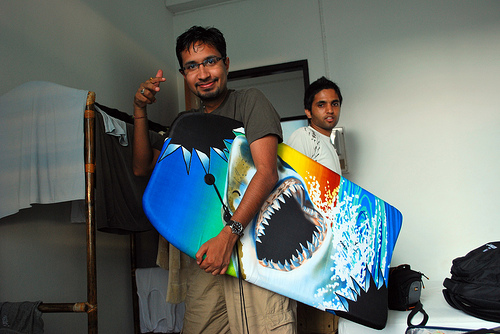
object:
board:
[136, 109, 404, 330]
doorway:
[226, 57, 308, 114]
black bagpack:
[441, 237, 498, 325]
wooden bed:
[0, 79, 167, 334]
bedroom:
[0, 0, 497, 334]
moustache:
[195, 77, 220, 90]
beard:
[197, 85, 220, 99]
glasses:
[179, 57, 226, 73]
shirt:
[285, 125, 348, 176]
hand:
[133, 68, 166, 107]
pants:
[182, 243, 299, 334]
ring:
[140, 88, 144, 93]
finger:
[149, 78, 166, 84]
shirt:
[131, 267, 187, 333]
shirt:
[92, 103, 129, 147]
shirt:
[87, 113, 164, 234]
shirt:
[0, 298, 47, 332]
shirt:
[0, 77, 90, 219]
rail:
[35, 300, 95, 314]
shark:
[221, 134, 333, 294]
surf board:
[140, 108, 403, 329]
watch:
[223, 216, 245, 238]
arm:
[194, 86, 284, 276]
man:
[282, 77, 342, 334]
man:
[131, 25, 298, 334]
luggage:
[387, 264, 428, 327]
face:
[181, 39, 227, 98]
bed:
[337, 288, 497, 334]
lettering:
[482, 244, 497, 252]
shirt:
[190, 87, 284, 148]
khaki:
[186, 264, 230, 334]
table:
[426, 304, 468, 332]